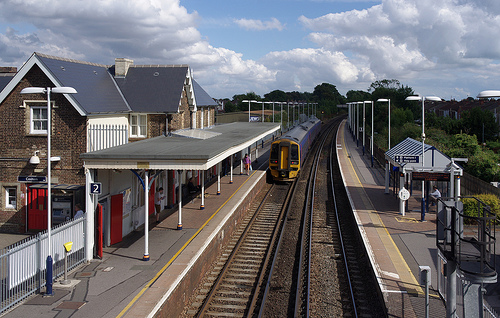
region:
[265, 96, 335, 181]
This is a train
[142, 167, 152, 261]
This is a pillar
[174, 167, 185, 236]
This is a pillar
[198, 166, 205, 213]
This is a pillar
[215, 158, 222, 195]
This is a pillar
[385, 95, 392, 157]
This is a pillar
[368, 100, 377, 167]
This is a pillar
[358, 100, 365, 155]
This is a pillar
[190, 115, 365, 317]
Rails near the train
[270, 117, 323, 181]
A train on the tracks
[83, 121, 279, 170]
The roof of the train platform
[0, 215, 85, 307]
A fence on the train platform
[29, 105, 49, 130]
A window on the building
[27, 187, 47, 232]
A door on the building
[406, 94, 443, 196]
A lamp post on the platform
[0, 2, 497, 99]
The sky above the train station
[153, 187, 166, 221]
A person standing on the platform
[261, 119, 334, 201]
yellow and blue train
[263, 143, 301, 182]
yellow front of train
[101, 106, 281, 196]
grey roof over platform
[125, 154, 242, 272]
white poles on platform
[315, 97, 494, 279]
grey poles with lights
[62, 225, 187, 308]
platform is dark grey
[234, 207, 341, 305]
grey gravel between tracks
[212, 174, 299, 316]
tracks are dark brown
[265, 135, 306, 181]
train is yellow and black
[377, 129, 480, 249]
bus shelter across from the platform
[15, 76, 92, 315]
two lights on one pole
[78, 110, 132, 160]
white fence on the building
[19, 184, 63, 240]
red door on the building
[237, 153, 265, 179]
person next to train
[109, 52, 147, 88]
chimney on the building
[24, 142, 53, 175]
light over the door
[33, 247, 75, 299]
bottom of pole is blue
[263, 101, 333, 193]
train on the tracks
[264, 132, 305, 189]
front of the train is yellow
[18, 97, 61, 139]
window on the side of the building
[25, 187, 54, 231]
red door on the building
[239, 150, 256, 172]
person standing by the train tracks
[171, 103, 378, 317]
two sets of train tracks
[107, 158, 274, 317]
yellow line on the ground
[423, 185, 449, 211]
person sitting down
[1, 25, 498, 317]
train at the station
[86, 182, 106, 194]
white number two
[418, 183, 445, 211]
man sitting in the station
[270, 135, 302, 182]
train is yellow and silver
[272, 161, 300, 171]
headlight on the train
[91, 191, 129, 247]
red door on the building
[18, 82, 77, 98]
light on the pole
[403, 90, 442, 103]
light on the pole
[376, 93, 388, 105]
light on the pole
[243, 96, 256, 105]
light on the pole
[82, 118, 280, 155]
the roof is gray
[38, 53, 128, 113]
the roof is gray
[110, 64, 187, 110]
the roof is gray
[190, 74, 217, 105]
the roof is gray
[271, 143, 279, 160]
window of a train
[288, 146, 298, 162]
window of a train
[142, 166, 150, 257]
the pole is white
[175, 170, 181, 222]
the pole is white